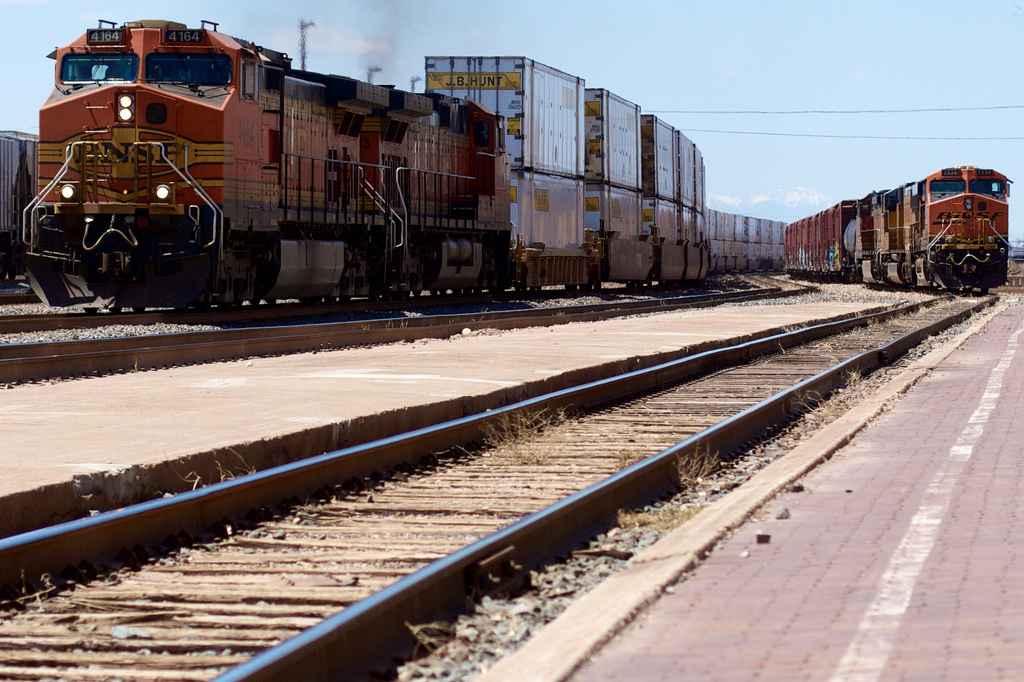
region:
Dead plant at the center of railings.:
[484, 405, 560, 466]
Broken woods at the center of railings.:
[2, 575, 293, 680]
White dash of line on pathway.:
[827, 326, 1021, 680]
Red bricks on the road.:
[680, 570, 840, 670]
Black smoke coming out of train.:
[340, 0, 411, 81]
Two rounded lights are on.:
[115, 94, 135, 121]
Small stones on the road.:
[748, 474, 816, 545]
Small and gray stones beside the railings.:
[444, 525, 625, 666]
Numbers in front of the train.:
[81, 29, 206, 46]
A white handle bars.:
[359, 168, 408, 257]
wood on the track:
[106, 623, 195, 658]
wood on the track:
[526, 445, 577, 468]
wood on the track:
[760, 361, 792, 371]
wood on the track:
[146, 319, 179, 335]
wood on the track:
[490, 458, 535, 471]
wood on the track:
[863, 310, 920, 334]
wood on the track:
[734, 372, 764, 379]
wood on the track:
[361, 538, 422, 567]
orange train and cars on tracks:
[41, 21, 727, 304]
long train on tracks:
[784, 160, 1019, 297]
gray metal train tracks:
[303, 415, 583, 594]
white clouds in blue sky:
[859, 61, 951, 135]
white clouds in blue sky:
[685, 55, 746, 82]